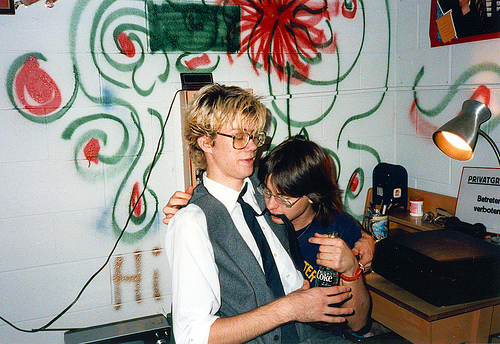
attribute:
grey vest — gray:
[184, 179, 307, 342]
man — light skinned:
[157, 82, 357, 341]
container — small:
[370, 157, 422, 207]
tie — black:
[237, 190, 300, 342]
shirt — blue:
[291, 211, 368, 328]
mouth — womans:
[265, 209, 286, 222]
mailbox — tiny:
[372, 153, 412, 208]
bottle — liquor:
[311, 231, 347, 306]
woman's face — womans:
[262, 180, 300, 227]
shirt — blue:
[288, 213, 361, 285]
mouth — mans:
[260, 199, 305, 227]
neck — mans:
[198, 167, 265, 203]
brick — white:
[45, 158, 108, 218]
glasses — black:
[253, 180, 310, 210]